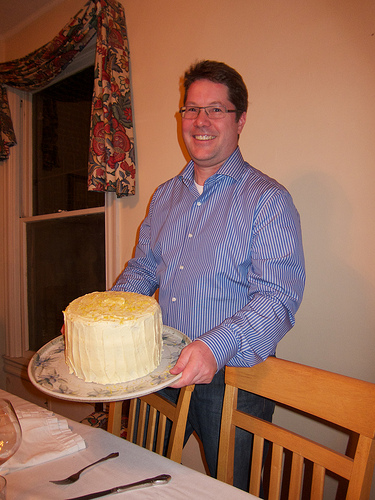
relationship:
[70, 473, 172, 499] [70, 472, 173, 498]
butter knife next to butter knife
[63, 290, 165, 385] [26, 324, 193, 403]
cake on design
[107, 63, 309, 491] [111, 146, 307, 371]
man wearing shirt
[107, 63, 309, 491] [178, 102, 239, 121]
man wearing glasses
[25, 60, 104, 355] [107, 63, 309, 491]
window to left of man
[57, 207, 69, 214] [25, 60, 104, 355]
lock on window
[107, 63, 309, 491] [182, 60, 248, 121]
man has hair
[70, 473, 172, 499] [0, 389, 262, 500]
butter knife on table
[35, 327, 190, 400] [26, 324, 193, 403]
design on design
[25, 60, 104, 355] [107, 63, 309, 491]
window next to man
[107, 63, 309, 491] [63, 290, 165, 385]
man holding cake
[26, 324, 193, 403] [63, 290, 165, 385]
design under cake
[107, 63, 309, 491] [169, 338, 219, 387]
man has left hand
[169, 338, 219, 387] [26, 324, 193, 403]
left hand holding design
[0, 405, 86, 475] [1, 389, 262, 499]
napkin on table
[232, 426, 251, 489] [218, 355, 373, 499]
opening on chair back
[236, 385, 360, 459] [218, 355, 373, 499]
opening on chair back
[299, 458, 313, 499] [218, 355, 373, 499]
opening on chair back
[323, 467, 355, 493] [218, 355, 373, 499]
opening on chair back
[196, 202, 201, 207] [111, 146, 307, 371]
button on shirt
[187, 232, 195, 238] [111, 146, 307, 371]
button on shirt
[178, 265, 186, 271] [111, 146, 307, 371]
button on shirt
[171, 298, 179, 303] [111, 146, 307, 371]
button on shirt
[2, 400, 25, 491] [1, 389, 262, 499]
glass on table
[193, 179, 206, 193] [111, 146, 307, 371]
t shirt under shirt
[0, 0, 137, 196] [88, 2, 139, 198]
curtain has right side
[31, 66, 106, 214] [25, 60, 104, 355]
pane of window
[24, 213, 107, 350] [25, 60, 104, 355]
pane of window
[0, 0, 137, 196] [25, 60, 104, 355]
curtain over window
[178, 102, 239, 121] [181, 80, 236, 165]
glasses on face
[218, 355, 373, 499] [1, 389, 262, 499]
chair back in front of table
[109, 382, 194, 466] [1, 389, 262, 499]
chair back in front of table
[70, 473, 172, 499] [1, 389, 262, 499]
butter knife sitting on table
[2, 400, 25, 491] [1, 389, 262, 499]
glass sitting on table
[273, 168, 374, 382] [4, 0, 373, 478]
shadow on wall